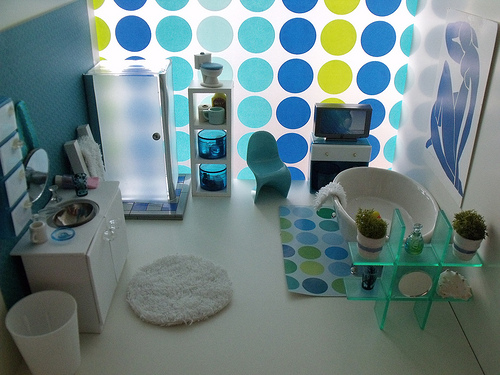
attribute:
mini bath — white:
[322, 162, 438, 259]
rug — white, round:
[139, 237, 301, 330]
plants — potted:
[353, 199, 487, 293]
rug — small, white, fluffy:
[130, 244, 249, 329]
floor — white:
[132, 222, 369, 373]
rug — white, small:
[124, 252, 234, 328]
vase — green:
[403, 222, 425, 257]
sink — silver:
[37, 182, 121, 260]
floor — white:
[78, 187, 440, 367]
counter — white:
[20, 183, 116, 296]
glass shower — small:
[87, 57, 188, 225]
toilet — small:
[194, 52, 222, 88]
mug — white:
[27, 218, 46, 244]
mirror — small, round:
[21, 143, 59, 193]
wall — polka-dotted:
[89, 0, 410, 206]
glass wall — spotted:
[227, 10, 304, 115]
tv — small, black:
[306, 94, 401, 151]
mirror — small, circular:
[24, 145, 54, 202]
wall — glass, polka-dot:
[90, 0, 420, 189]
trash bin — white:
[6, 288, 81, 374]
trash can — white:
[4, 286, 84, 373]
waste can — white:
[2, 288, 88, 373]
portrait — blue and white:
[354, 17, 498, 177]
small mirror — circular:
[22, 148, 50, 206]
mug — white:
[24, 216, 52, 247]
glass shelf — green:
[352, 254, 442, 329]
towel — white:
[310, 181, 349, 211]